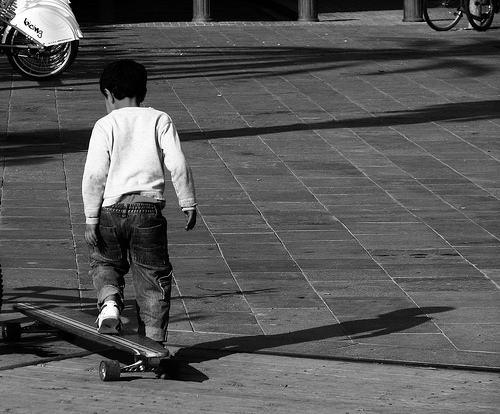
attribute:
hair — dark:
[95, 63, 149, 100]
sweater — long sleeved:
[80, 107, 199, 229]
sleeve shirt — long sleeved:
[154, 114, 198, 210]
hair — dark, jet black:
[96, 57, 148, 100]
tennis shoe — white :
[89, 301, 124, 335]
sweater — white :
[94, 104, 208, 211]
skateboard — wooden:
[8, 296, 168, 378]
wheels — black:
[1, 315, 123, 390]